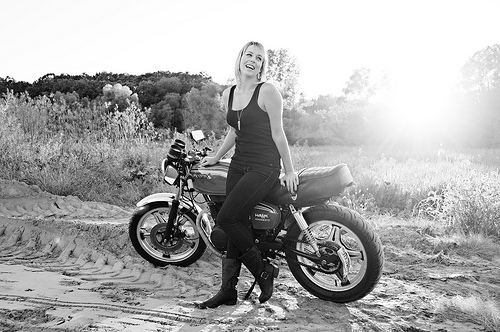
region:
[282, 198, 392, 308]
black motorcycle tire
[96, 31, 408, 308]
woman leaning on a motorcycle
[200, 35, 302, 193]
blonde woman with black shirt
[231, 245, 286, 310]
black leather boot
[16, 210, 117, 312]
tire tracks in the dirt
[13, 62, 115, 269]
bushes and trees along roadside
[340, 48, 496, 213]
sunlight shining through trees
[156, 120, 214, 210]
handle bars of motorcycle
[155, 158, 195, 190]
rear view mirror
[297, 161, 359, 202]
back seat of motorcycle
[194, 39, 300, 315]
a smiling woman sitting on a motorcycle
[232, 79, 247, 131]
a necklace around a woman's neck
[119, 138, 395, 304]
a motorcycle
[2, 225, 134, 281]
tire tracks on a dirt road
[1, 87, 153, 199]
brush alongside a dirt road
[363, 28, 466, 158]
the reflection of sunlight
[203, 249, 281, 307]
dark boots with a buckle worn by a woman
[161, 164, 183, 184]
a side view mirror on the motorcycle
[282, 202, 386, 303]
the rear wheel of the motorcycle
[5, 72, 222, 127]
a stand of trees behind an open field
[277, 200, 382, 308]
tire on a motorcycle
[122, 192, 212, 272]
tire on a motorcycle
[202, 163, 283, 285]
pair of black pants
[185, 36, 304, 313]
lady wearing black pants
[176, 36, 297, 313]
lady wearing black tank top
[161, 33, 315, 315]
lady with blonde hair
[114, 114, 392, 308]
motorcycle on a dirt road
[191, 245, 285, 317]
pair of black boots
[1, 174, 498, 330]
dirt road near a field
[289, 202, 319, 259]
shock on a motorcycle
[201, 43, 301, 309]
the woman standing in front of a motorcycle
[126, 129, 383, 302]
the motorcycle behind the woman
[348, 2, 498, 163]
the bright sun shining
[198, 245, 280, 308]
the boots on the woman's feet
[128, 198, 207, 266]
the front tire on the motorcycle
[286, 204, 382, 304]
the back tire of the motorcycle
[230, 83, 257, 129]
the necklace around the woman's neck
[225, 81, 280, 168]
the tanktop on the woman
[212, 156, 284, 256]
the long pants on the woman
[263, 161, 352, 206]
the seat of the motorcycle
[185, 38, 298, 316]
lady near a motorcycle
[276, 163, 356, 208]
seat on a motorcycle